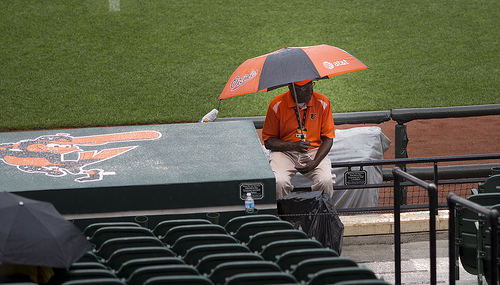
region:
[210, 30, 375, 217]
man sitting on a railing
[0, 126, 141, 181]
logo of a baseball team on the top of a dugout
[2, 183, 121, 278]
black umbrella being used by a fan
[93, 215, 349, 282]
empty seats in a baseball stadium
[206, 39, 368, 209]
man holding a black and orange umbrella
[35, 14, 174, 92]
green field of a baseball diamond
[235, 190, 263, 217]
a plastic drink bottle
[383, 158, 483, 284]
railing to hold on to in a baseball stadium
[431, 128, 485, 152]
dirt of the baseball diamond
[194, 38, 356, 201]
man waiting in the rain and holding umbrella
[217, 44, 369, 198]
Man sitting under an umbrella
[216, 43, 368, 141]
Large orange and black umbrella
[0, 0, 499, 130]
Green grass on a baseball field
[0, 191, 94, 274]
Large black umbrella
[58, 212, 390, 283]
Green seats in the stands at a baseball field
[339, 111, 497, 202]
Sandy warning track at a baseball field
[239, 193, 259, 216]
Bottle of water in a cup holder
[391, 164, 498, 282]
Two black metal hand rails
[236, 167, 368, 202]
Two small signs with words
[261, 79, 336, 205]
Man wearing tan pants and an orange shirt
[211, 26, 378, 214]
man holding an umbrella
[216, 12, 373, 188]
man wearing a cap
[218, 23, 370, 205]
man wearing orange shirt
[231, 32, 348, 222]
man wearing khaki pants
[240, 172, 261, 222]
bottle of water in holder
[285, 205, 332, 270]
green seats in a stadium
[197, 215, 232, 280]
green seats in a stadium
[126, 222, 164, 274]
green seats in a stadium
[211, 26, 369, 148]
orange and black umbrella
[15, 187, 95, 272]
black umbrella in stadium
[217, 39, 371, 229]
black man holding orange umbrella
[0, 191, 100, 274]
large black open umbrella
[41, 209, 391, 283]
parallel rows of folding chairs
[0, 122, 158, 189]
orange and black cartoon team mascot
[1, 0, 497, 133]
green grass on playing field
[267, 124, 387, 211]
beige waterproof tarp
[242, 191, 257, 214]
water bottle with blue label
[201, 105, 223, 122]
plastic water bottle with red label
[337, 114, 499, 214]
dirt area of playing field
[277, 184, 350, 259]
snack cart covered with black tarp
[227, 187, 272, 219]
water bottle in cup holder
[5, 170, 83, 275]
black umbrella in seats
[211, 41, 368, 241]
man holding orange and black umbrella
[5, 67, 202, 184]
team logo on dugout roof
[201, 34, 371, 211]
man wearing orange and black lanyard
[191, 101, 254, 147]
empty bottle on railing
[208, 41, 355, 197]
man wearing glasses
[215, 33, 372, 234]
man wearing hat with orange bill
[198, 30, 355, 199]
man wearing white undershirt